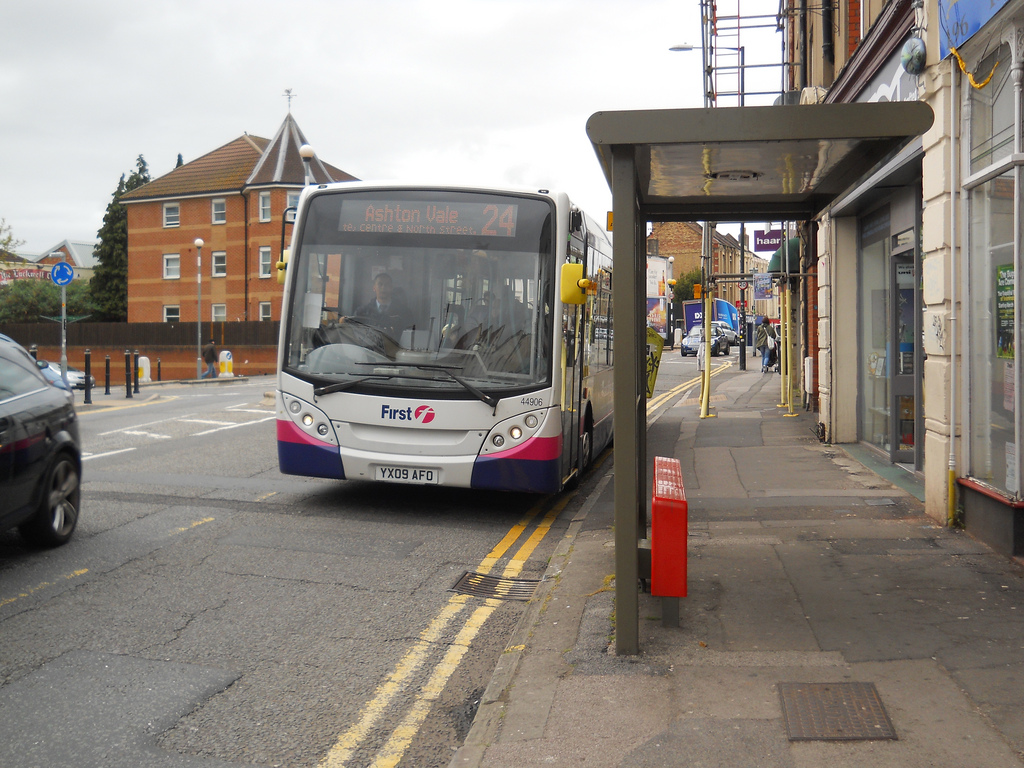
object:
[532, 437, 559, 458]
pink stripe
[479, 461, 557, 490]
purple stripe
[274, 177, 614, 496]
bus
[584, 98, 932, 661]
bus stop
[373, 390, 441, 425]
logo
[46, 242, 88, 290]
sign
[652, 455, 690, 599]
red object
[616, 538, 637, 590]
pole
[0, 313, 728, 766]
road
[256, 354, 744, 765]
yellow lines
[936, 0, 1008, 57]
blue sign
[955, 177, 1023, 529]
door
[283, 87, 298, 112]
weather vane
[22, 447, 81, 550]
tire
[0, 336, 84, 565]
car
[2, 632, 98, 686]
crack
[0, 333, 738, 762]
street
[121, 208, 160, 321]
wall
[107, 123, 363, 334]
building